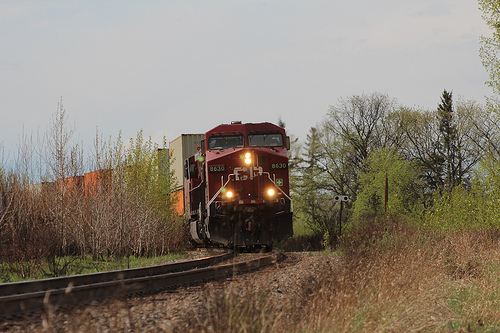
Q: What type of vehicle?
A: Train.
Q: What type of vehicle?
A: Train.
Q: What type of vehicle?
A: Train.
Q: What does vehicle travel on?
A: Tracks.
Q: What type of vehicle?
A: Train.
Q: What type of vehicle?
A: Train.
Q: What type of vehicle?
A: Train.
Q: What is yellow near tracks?
A: Grass.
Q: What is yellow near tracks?
A: Grass.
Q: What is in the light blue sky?
A: Clouds.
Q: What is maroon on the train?
A: The locomotive.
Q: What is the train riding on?
A: Train tracks.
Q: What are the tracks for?
A: To hold the train.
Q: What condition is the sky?
A: Clear but gray.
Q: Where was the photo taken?
A: In front of the train tracks.